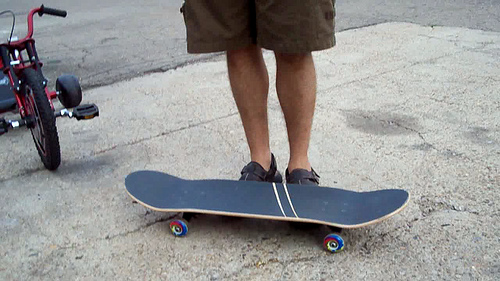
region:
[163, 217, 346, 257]
multi colored wheels on the skateboard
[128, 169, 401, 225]
black skateboard with two white stripes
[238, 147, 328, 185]
black shoes worn by man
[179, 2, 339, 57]
brown shorts worn by man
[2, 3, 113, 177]
bicycle on the sidewalk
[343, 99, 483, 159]
stains on the cement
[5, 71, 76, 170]
wheels on the bicycle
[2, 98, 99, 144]
black pedals on the bicycle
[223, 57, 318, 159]
legs of the man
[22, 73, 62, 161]
black front tire of the bicycle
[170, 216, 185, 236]
the multi colored wheel of the skateboard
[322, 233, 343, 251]
the multi colored wheel of the skateboard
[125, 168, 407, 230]
the black and white skateboard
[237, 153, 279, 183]
the brown shoe on the foot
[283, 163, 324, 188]
the brown shoe on the foot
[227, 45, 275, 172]
the leg of a man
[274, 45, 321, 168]
the leg of a man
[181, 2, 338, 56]
the brown shorts of the man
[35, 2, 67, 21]
the black handle of the bike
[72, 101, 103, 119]
the black pedal of the bike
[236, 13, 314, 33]
Person wearing brown shorts.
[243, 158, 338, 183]
Person wearing sandals on feet.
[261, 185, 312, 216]
White strip on top of skateboard.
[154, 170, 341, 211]
Top of skateboard is black.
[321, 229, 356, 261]
Red and blue wheel on skateboard.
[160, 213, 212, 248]
Red and blue wheel on skateboard.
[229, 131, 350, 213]
Person standing on concrete.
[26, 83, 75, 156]
Black tire on front of bike.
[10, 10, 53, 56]
Red handle bar on bike.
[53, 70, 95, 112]
Black wheel on back of bike.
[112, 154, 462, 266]
a black and white skateboard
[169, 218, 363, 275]
blue and red wheels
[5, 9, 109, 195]
a little red bike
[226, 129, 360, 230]
brown sandals on feet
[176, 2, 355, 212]
brown shorts on legs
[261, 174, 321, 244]
two white lines on skateboard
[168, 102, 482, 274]
cracks in the pavement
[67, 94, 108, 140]
black pedal on bike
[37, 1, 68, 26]
black handle bar grip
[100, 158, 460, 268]
a skateboard on the ground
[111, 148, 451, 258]
A gray and white striped skateboard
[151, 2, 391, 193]
A man's legs and green shorts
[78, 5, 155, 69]
A gray asphalt road surface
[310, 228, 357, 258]
The wheel of a skateboard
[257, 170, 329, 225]
White stripes on a skateboard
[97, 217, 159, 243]
A crack in the concrete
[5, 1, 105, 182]
A red and black tricycle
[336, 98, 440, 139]
A spot on the pavement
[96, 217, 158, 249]
A crack in the pavement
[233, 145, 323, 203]
A man's shoes